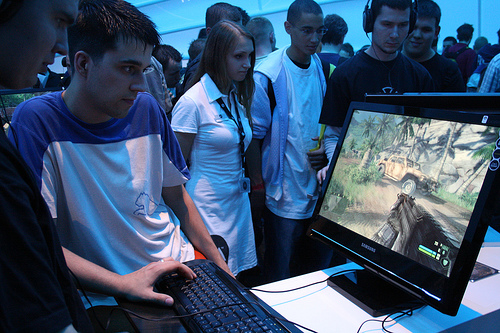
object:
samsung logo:
[358, 242, 376, 254]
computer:
[147, 100, 499, 333]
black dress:
[0, 122, 87, 333]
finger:
[152, 263, 193, 286]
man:
[440, 25, 480, 89]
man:
[242, 12, 278, 63]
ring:
[158, 258, 165, 263]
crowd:
[0, 4, 500, 333]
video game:
[311, 102, 500, 314]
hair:
[66, 0, 167, 59]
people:
[248, 0, 337, 281]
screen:
[304, 99, 499, 311]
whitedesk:
[252, 249, 499, 331]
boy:
[317, 0, 432, 179]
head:
[358, 0, 417, 56]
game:
[294, 94, 495, 309]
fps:
[353, 132, 460, 242]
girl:
[172, 18, 260, 280]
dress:
[168, 74, 260, 271]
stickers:
[478, 129, 499, 171]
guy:
[7, 3, 238, 297]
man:
[0, 0, 198, 333]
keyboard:
[157, 259, 277, 327]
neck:
[207, 78, 244, 97]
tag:
[210, 85, 255, 194]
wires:
[243, 269, 421, 330]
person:
[411, 3, 441, 85]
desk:
[184, 240, 500, 333]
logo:
[128, 186, 175, 226]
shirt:
[11, 91, 196, 301]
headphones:
[360, 0, 423, 32]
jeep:
[369, 150, 445, 195]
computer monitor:
[351, 79, 498, 126]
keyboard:
[147, 255, 309, 333]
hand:
[117, 254, 196, 309]